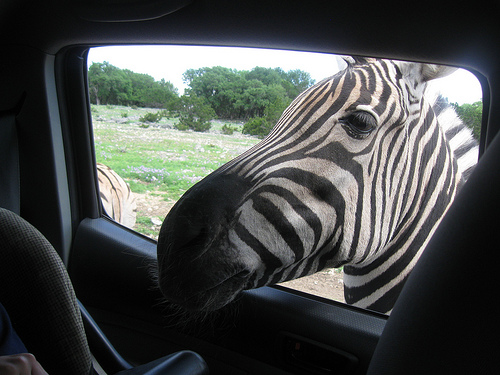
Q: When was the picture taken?
A: During daylight.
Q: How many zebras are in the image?
A: Two.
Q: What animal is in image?
A: Zebra.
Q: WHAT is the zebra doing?
A: Looking in vehicle.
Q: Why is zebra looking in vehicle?
A: For food.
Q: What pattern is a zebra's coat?
A: Stripes.